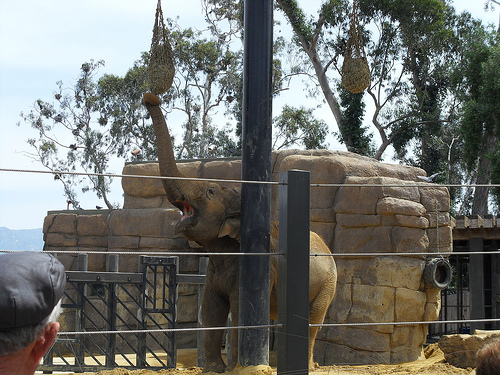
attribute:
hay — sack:
[363, 326, 416, 365]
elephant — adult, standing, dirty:
[128, 97, 327, 362]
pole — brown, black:
[239, 2, 286, 180]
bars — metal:
[70, 279, 181, 366]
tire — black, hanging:
[418, 251, 464, 297]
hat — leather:
[1, 256, 59, 350]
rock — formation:
[325, 300, 430, 366]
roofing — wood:
[193, 145, 239, 168]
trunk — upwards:
[139, 89, 194, 200]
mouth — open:
[173, 201, 199, 225]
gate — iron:
[69, 261, 93, 310]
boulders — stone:
[71, 200, 144, 244]